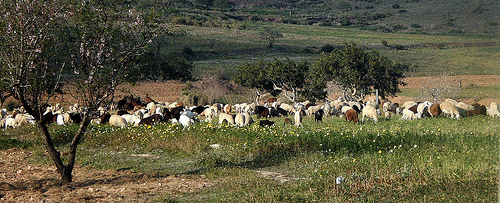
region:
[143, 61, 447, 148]
group of animals in field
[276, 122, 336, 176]
flowers in meadow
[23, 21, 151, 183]
tree next to animals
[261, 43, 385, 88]
two trees in distance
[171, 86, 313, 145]
many different colored animals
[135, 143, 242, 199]
brown dirt and green grass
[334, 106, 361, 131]
brown animal in meadow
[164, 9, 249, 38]
bushes in the background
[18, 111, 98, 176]
two branches of tree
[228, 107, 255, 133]
white animal in meadow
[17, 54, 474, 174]
many cattle in pasture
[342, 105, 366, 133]
brown cow in pasture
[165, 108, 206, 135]
white cow in pasture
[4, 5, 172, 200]
one tree with purple flowers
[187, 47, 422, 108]
row of trees in center of photo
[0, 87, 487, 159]
many cows in grass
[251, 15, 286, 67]
one tree alone in background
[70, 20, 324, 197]
green grass with white flowers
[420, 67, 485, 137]
tan cow in pasture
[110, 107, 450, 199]
flowers in green grass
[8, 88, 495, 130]
herd of animals in the grass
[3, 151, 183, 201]
patch of brown dirt in the green grass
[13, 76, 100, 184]
tall and skinny tree trunk that forks near the bottom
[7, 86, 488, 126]
animals laying in the grass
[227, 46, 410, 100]
two green treetops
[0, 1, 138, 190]
tree stemming from brown patch of dirt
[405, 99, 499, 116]
brown, white, and tan animals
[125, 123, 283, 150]
yellow dandelions growing in the grass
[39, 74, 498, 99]
brown dirt path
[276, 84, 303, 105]
antlers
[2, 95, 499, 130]
Sheep in a field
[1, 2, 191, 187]
Tree standing in foreground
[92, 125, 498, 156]
Animals are beside many flowers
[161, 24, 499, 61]
Grassy hill behind the sheep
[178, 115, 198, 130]
White sheep in foreground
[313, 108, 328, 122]
Black sheep are plentiful in the herd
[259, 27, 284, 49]
Small tree in background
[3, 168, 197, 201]
Dirt near base of tree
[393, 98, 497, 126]
These sheep are eating grass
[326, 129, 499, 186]
Flowers litter the landscape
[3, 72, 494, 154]
a herd of cattle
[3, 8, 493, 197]
cattle in a field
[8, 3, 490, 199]
cattle grazing on grass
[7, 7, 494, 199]
cattle on a ranch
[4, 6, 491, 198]
farm cattle grazing in a field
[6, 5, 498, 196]
cattle in the foothills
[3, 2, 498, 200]
a large group of cattle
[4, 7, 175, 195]
cattle behind a small tree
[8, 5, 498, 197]
cattle standing in a pasture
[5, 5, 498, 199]
a herd of animals in a field